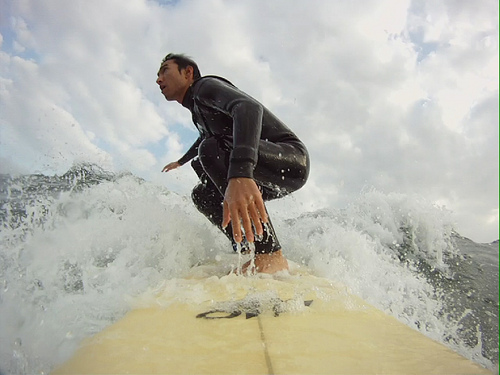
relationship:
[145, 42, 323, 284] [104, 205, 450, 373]
man on board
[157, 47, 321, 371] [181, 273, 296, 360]
surfer on board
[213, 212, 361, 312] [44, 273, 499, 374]
barefeet on board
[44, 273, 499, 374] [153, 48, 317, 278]
board under man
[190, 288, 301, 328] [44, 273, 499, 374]
writing on board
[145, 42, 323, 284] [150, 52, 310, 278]
man wears wetsuit man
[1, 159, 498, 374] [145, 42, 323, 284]
waves around man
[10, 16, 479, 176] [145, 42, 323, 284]
sky behind man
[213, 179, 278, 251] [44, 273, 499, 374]
hand point board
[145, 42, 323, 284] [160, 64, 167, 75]
man has eyes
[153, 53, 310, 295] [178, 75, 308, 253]
surfer wears wetsuit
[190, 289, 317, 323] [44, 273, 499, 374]
text on board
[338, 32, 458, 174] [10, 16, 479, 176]
cloud in sky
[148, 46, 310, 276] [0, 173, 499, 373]
surfer on wave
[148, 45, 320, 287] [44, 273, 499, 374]
surfer on board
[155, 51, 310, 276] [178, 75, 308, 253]
rider wears wetsuit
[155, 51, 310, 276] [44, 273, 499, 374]
rider on board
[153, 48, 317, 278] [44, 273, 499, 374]
man on board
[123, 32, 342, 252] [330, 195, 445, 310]
man in water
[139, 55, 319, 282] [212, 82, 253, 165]
man wears wetsuit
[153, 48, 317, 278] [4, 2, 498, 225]
man under cloudy sky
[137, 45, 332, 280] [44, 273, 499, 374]
person on board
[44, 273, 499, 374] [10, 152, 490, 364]
board on water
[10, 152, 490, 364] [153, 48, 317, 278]
water splashing on man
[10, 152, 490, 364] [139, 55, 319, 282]
water splashing on man